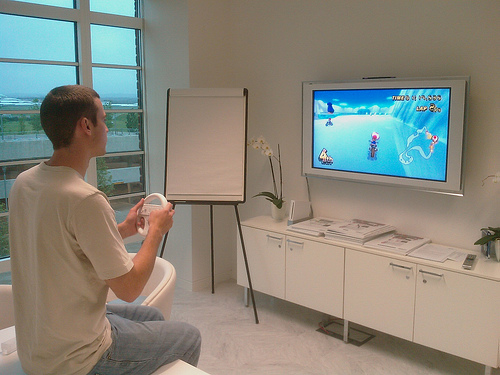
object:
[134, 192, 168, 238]
game controller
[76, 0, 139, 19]
window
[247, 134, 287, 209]
flowers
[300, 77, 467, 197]
tv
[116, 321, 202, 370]
leg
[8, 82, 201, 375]
man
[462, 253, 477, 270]
remote control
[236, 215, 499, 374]
cabinet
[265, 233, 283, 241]
handle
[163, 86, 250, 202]
paper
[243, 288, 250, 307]
cabinet leg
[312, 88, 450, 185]
game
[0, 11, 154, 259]
windows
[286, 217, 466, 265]
papers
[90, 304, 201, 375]
blue jeans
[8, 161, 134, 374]
shirt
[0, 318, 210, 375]
desk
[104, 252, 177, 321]
chair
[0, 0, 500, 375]
office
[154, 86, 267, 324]
easel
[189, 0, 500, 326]
wall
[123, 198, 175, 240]
hands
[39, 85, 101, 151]
hair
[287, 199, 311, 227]
wii console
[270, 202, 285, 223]
vase